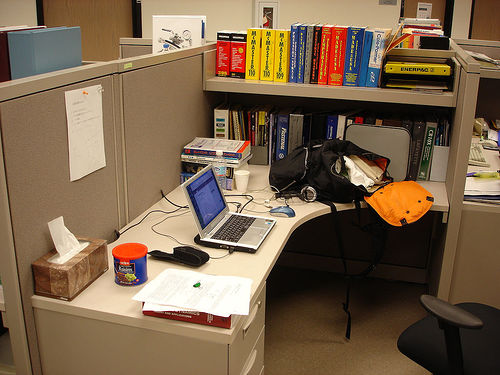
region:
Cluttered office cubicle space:
[8, 13, 496, 368]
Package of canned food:
[110, 242, 151, 285]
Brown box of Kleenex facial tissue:
[21, 219, 110, 302]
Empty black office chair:
[394, 273, 499, 371]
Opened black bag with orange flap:
[266, 133, 433, 223]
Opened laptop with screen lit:
[177, 163, 278, 250]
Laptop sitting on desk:
[183, 164, 278, 251]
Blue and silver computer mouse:
[266, 204, 298, 218]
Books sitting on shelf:
[216, 23, 384, 85]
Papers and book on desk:
[133, 267, 253, 328]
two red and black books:
[208, 26, 264, 111]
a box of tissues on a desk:
[7, 205, 149, 337]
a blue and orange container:
[91, 230, 181, 330]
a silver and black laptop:
[155, 150, 300, 262]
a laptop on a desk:
[122, 160, 308, 286]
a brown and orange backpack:
[245, 130, 460, 250]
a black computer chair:
[371, 260, 493, 370]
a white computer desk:
[45, 155, 377, 350]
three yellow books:
[231, 17, 306, 97]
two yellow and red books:
[307, 20, 359, 108]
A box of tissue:
[28, 213, 109, 301]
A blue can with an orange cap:
[111, 240, 148, 286]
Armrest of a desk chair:
[419, 294, 483, 331]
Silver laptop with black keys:
[181, 163, 278, 251]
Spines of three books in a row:
[248, 28, 288, 81]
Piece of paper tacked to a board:
[64, 83, 105, 183]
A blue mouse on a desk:
[269, 203, 296, 219]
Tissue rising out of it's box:
[46, 213, 81, 258]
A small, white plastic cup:
[234, 168, 250, 192]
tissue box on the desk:
[12, 211, 109, 307]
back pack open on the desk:
[272, 140, 435, 227]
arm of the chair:
[412, 282, 494, 337]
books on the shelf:
[215, 25, 387, 85]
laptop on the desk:
[179, 159, 279, 257]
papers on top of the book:
[155, 271, 244, 315]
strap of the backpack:
[320, 220, 392, 354]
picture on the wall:
[259, 1, 282, 28]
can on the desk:
[110, 239, 150, 291]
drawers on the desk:
[242, 315, 267, 361]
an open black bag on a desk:
[268, 139, 440, 229]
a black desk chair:
[396, 290, 498, 372]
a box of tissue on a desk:
[30, 214, 108, 301]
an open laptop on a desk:
[179, 163, 275, 255]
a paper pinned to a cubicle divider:
[58, 79, 107, 185]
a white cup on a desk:
[233, 167, 251, 194]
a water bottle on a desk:
[209, 146, 230, 194]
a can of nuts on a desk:
[112, 240, 149, 289]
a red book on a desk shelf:
[327, 22, 348, 88]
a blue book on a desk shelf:
[342, 24, 366, 86]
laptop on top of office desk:
[184, 159, 274, 253]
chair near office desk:
[396, 275, 499, 372]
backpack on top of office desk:
[275, 136, 435, 341]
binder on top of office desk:
[384, 59, 447, 82]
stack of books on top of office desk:
[181, 132, 251, 185]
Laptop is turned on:
[177, 163, 284, 255]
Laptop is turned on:
[176, 156, 277, 257]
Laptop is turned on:
[178, 155, 278, 253]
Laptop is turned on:
[181, 163, 282, 254]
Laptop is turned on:
[181, 160, 278, 261]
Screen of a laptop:
[188, 166, 222, 223]